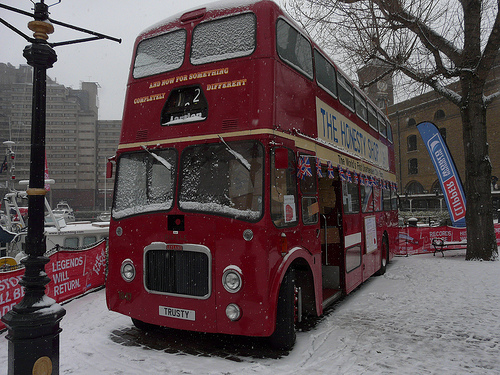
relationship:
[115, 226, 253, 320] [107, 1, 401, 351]
lights on bus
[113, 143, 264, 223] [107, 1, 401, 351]
windshield on bus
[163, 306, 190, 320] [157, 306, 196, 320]
trusty on sign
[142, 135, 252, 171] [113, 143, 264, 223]
wipers on windshield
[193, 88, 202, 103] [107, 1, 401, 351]
2 on bus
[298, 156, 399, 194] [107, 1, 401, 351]
flags on bus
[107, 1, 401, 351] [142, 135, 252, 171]
bus has wipers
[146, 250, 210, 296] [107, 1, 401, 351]
grill on bus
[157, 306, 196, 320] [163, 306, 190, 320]
sign that says trusty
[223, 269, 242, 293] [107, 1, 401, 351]
headlight on bus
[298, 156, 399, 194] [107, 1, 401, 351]
flags on side of bus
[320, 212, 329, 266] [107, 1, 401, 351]
bar in bus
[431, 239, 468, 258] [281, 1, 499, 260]
bench near tree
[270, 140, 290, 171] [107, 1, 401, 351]
mirror on bus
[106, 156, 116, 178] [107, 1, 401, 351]
mirror on left side of bus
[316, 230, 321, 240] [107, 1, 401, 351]
handle on bus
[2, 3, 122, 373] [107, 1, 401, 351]
post in front of bus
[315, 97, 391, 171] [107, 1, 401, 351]
sign on side of bus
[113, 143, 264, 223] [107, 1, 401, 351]
windshield of bus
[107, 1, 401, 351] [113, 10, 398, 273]
bus has windows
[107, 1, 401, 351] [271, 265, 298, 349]
bus has a tire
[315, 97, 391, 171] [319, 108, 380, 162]
sign says honesty shop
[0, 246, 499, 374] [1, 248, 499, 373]
snow on ground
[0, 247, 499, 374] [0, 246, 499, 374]
footprints on snow